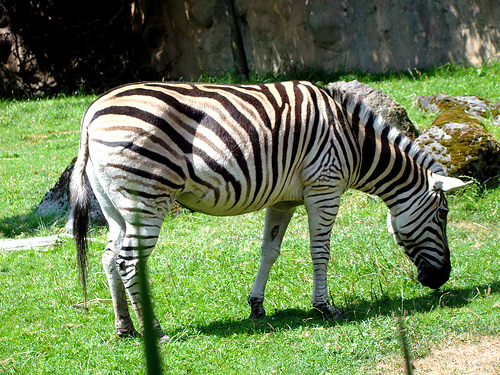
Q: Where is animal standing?
A: Field.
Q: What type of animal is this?
A: Zebra.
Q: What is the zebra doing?
A: Eating.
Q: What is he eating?
A: Grass.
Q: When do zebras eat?
A: When hungry.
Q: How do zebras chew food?
A: Teeth.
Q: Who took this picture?
A: Photographer.